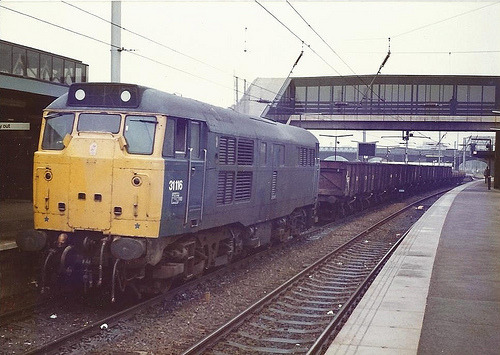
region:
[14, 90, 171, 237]
The front part of the yellow train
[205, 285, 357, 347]
Train tracks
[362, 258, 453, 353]
The train platform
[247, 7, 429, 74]
Train cables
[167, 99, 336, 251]
the side of the train is gray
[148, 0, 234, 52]
a White cloudy sky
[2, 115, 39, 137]
Train station sign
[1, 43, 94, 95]
windows from the train sation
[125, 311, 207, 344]
Gravel along side the train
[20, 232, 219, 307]
Train wheels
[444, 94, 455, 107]
part of a window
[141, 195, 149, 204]
front part of a train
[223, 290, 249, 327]
edge of a railway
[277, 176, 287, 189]
side of a train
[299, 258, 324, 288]
steel of a way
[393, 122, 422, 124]
part of a bridge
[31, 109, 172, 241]
front of the train engine is yellow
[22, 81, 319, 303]
gray and yellow train engine on the track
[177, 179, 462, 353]
track next to track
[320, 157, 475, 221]
engine pulling train cars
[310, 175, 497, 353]
white line pained on platform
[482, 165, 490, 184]
person standing on platform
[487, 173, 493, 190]
short post on the platform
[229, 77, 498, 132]
pedestrian bridge over train tack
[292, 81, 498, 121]
glass window on side of pedestrian bridge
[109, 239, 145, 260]
oval bumpers on front of engine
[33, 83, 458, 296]
a train is on the tracks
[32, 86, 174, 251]
the front of the train is yellow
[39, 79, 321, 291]
the engine is black with white markings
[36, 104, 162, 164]
the windows on the engine has windshield wipers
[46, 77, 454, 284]
the train's engine is pulling cargo cars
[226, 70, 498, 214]
a pedrestrian overpass goes over the tracks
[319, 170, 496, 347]
a platform is next to the tracks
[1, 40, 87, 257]
a terminal is next to the tracks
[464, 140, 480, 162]
a signal light is near the tracks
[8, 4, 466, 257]
electric lines are over the tracks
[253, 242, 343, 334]
The rail road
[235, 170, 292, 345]
The rail road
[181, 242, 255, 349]
The rail road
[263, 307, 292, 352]
The rail road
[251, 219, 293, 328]
The rail road